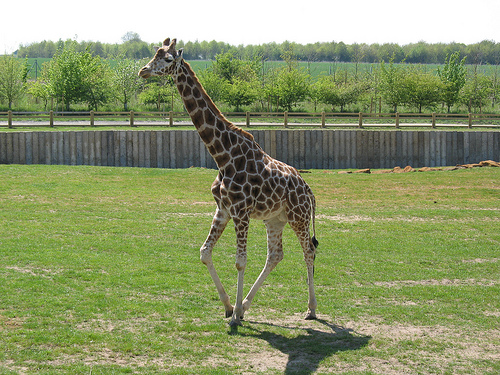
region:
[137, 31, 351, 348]
one tall brown and tan giraffe walking on grass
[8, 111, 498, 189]
brown wooden fence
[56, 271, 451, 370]
brown spots in green grass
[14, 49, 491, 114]
line of green trees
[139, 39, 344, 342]
giraffe facing left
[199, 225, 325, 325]
white giraffe legs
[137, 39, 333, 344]
one giraffe walking to left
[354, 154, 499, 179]
pile of brown rocks laying in grass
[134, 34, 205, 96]
white face with small brown spots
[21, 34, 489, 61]
group of green trees in distance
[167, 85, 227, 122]
neck of a giraffe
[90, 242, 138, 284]
part of some grass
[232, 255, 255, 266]
part of a knee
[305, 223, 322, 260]
tail of a giraffe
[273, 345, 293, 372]
part of a shade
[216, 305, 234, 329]
part of a hoof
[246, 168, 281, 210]
stomach of a giraffe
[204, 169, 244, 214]
chest of a giraffe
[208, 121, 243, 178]
beck of a giraffe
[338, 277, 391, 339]
part of a ground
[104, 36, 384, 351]
A giraffe in the grass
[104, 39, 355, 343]
A giraffe walking in the grass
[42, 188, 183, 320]
green grass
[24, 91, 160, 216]
A wood fence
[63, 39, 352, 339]
A giraffe walking in a zoo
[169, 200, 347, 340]
The legs of a giraffe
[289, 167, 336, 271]
The tails of a giraffe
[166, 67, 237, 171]
The neck of a giraffe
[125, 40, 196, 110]
The head of a giraffe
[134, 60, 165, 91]
The nose of a giraffe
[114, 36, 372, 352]
A giraffe in a zoo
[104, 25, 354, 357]
A giraffe on grass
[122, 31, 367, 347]
A giraffe walking on grass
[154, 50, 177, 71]
The eye of a giraffe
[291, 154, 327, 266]
The tail of a giraffe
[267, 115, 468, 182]
A wood fence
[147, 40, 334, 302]
this is a giraffe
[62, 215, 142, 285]
this is a grass area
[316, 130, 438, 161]
this is a wall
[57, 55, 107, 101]
this is a tree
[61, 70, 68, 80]
the tree has green leaves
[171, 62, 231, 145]
the giraffe has long neck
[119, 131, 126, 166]
this is a wood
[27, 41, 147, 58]
this is a forest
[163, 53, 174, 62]
this is the eye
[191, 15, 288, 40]
this is the cloud